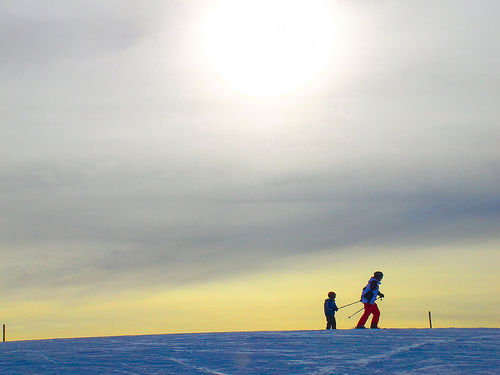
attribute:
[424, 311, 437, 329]
stick — brown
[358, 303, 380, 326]
pants — red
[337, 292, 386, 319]
pole — ski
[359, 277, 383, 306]
jacket — blue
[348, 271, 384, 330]
helmet — black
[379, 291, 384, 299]
person — skiing, walking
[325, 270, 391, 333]
people — walking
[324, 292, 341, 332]
kid — little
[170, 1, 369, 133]
sun — shining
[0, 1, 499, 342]
sky — cloudy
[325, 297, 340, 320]
coat — blue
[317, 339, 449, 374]
line — horizontal